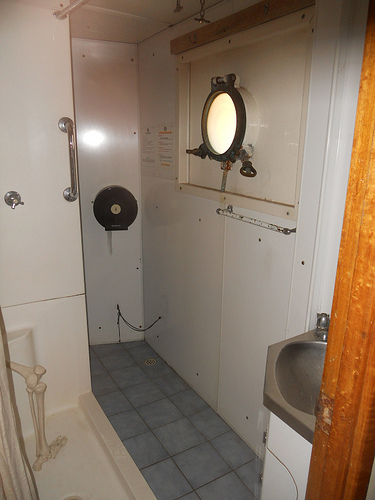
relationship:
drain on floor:
[124, 355, 184, 374] [91, 332, 264, 498]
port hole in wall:
[202, 83, 244, 162] [2, 5, 85, 323]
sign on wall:
[139, 123, 159, 179] [136, 2, 330, 460]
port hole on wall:
[202, 90, 237, 155] [136, 2, 368, 460]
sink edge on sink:
[259, 339, 284, 415] [258, 339, 280, 412]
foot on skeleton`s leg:
[32, 435, 68, 470] [4, 359, 66, 472]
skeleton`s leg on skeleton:
[4, 359, 66, 472] [8, 355, 70, 475]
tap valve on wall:
[4, 188, 25, 209] [1, 0, 94, 447]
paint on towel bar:
[213, 208, 288, 235] [210, 200, 312, 256]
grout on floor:
[89, 337, 261, 497] [91, 332, 264, 498]